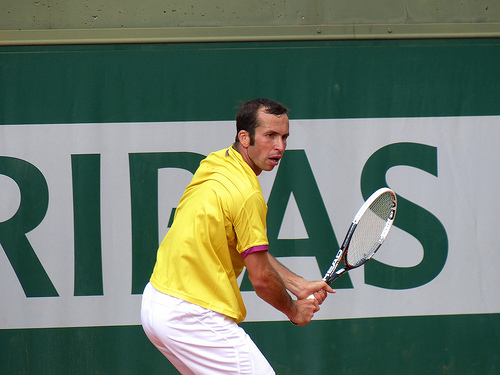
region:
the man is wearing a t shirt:
[151, 146, 275, 318]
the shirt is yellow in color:
[156, 142, 273, 327]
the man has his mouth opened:
[266, 150, 282, 167]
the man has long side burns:
[246, 127, 257, 148]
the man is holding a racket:
[278, 188, 398, 330]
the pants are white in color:
[133, 280, 288, 374]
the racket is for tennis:
[300, 189, 400, 318]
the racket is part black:
[317, 220, 383, 286]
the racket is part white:
[351, 180, 398, 245]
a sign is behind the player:
[1, 108, 496, 339]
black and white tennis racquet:
[326, 168, 414, 296]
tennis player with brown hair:
[216, 82, 298, 182]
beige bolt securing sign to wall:
[306, 20, 339, 42]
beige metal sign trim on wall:
[0, 22, 298, 45]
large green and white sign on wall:
[0, 39, 141, 374]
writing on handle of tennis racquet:
[324, 245, 346, 282]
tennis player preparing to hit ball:
[147, 71, 437, 373]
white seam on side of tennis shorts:
[221, 333, 251, 373]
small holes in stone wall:
[144, 3, 249, 22]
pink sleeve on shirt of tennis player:
[229, 234, 271, 264]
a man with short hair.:
[223, 78, 317, 183]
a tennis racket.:
[286, 170, 427, 327]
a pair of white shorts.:
[127, 278, 289, 370]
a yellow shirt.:
[132, 133, 292, 328]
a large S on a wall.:
[355, 126, 460, 296]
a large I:
[60, 133, 115, 320]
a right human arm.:
[235, 230, 330, 330]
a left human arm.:
[247, 245, 342, 332]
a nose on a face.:
[270, 131, 287, 157]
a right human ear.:
[233, 115, 254, 155]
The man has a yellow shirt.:
[140, 129, 265, 303]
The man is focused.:
[142, 58, 384, 370]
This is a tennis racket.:
[305, 169, 425, 314]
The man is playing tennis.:
[80, 72, 444, 367]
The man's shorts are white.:
[128, 278, 272, 373]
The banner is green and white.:
[26, 60, 163, 350]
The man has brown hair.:
[226, 77, 284, 154]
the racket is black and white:
[331, 189, 416, 302]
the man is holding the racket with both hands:
[280, 266, 360, 348]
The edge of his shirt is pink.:
[235, 227, 285, 269]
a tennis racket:
[338, 189, 402, 269]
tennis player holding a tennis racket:
[289, 268, 334, 330]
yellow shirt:
[163, 165, 230, 313]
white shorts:
[152, 303, 232, 373]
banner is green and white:
[3, 60, 136, 371]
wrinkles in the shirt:
[203, 171, 242, 204]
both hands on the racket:
[288, 273, 333, 325]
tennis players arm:
[247, 268, 298, 308]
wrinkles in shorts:
[182, 323, 233, 358]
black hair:
[241, 108, 261, 129]